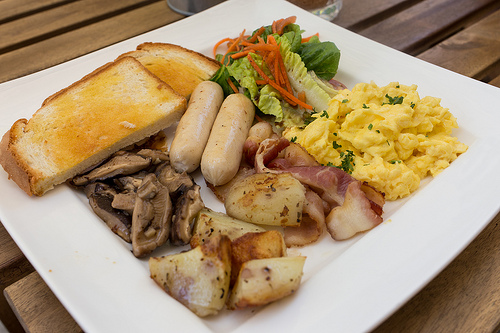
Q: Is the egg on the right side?
A: Yes, the egg is on the right of the image.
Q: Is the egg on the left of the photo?
A: No, the egg is on the right of the image.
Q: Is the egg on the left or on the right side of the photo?
A: The egg is on the right of the image.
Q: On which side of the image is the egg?
A: The egg is on the right of the image.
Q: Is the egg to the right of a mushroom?
A: Yes, the egg is to the right of a mushroom.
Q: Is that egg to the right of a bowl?
A: No, the egg is to the right of a mushroom.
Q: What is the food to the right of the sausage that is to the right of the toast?
A: The food is an egg.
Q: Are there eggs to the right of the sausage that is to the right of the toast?
A: Yes, there is an egg to the right of the sausage.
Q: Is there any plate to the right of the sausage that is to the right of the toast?
A: No, there is an egg to the right of the sausage.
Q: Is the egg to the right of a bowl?
A: No, the egg is to the right of the sausage.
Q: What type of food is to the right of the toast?
A: The food is an egg.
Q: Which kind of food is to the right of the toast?
A: The food is an egg.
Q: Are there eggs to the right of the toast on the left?
A: Yes, there is an egg to the right of the toast.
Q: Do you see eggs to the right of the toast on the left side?
A: Yes, there is an egg to the right of the toast.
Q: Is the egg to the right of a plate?
A: No, the egg is to the right of a toast.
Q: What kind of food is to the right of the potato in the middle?
A: The food is an egg.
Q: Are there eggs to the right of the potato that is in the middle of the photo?
A: Yes, there is an egg to the right of the potato.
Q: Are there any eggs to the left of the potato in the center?
A: No, the egg is to the right of the potato.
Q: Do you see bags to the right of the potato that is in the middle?
A: No, there is an egg to the right of the potato.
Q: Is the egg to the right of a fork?
A: No, the egg is to the right of the potato.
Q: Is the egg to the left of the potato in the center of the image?
A: No, the egg is to the right of the potato.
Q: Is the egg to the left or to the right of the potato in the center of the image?
A: The egg is to the right of the potato.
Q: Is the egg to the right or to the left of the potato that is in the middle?
A: The egg is to the right of the potato.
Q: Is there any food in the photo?
A: Yes, there is food.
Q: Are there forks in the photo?
A: No, there are no forks.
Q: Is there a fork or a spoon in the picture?
A: No, there are no forks or spoons.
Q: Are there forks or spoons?
A: No, there are no forks or spoons.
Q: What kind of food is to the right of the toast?
A: The food is a sausage.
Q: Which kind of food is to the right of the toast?
A: The food is a sausage.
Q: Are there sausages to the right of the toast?
A: Yes, there is a sausage to the right of the toast.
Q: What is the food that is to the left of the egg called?
A: The food is a sausage.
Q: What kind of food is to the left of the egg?
A: The food is a sausage.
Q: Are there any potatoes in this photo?
A: Yes, there is a potato.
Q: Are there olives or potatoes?
A: Yes, there is a potato.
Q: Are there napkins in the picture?
A: No, there are no napkins.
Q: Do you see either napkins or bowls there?
A: No, there are no napkins or bowls.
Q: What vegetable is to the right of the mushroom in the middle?
A: The vegetable is a potato.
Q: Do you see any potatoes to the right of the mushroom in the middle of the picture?
A: Yes, there is a potato to the right of the mushroom.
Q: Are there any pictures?
A: No, there are no pictures.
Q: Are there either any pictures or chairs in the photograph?
A: No, there are no pictures or chairs.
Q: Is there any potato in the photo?
A: Yes, there is a potato.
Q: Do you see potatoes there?
A: Yes, there is a potato.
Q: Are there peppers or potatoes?
A: Yes, there is a potato.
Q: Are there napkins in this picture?
A: No, there are no napkins.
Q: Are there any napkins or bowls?
A: No, there are no napkins or bowls.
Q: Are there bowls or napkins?
A: No, there are no napkins or bowls.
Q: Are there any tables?
A: Yes, there is a table.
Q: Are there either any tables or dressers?
A: Yes, there is a table.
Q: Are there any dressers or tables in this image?
A: Yes, there is a table.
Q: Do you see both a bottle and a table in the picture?
A: No, there is a table but no bottles.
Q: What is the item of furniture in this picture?
A: The piece of furniture is a table.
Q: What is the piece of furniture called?
A: The piece of furniture is a table.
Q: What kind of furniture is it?
A: The piece of furniture is a table.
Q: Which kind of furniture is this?
A: This is a table.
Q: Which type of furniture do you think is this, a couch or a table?
A: This is a table.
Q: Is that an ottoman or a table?
A: That is a table.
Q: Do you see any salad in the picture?
A: Yes, there is salad.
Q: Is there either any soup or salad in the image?
A: Yes, there is salad.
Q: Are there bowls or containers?
A: No, there are no containers or bowls.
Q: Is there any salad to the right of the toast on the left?
A: Yes, there is salad to the right of the toast.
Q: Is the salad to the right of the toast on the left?
A: Yes, the salad is to the right of the toast.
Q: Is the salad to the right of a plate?
A: No, the salad is to the right of the toast.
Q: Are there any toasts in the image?
A: Yes, there is a toast.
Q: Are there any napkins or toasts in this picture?
A: Yes, there is a toast.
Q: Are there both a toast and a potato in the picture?
A: Yes, there are both a toast and a potato.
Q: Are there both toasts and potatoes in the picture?
A: Yes, there are both a toast and a potato.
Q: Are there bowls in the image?
A: No, there are no bowls.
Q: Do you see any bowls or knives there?
A: No, there are no bowls or knives.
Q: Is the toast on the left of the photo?
A: Yes, the toast is on the left of the image.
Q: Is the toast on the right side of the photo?
A: No, the toast is on the left of the image.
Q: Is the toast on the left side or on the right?
A: The toast is on the left of the image.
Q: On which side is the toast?
A: The toast is on the left of the image.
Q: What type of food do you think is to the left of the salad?
A: The food is a toast.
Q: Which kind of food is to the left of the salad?
A: The food is a toast.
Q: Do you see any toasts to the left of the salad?
A: Yes, there is a toast to the left of the salad.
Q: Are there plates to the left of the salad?
A: No, there is a toast to the left of the salad.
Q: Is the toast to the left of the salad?
A: Yes, the toast is to the left of the salad.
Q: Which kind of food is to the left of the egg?
A: The food is a toast.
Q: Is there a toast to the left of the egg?
A: Yes, there is a toast to the left of the egg.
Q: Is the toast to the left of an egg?
A: Yes, the toast is to the left of an egg.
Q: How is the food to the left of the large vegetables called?
A: The food is a toast.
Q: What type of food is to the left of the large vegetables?
A: The food is a toast.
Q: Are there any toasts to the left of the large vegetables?
A: Yes, there is a toast to the left of the vegetables.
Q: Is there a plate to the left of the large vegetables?
A: No, there is a toast to the left of the veggies.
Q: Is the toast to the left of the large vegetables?
A: Yes, the toast is to the left of the veggies.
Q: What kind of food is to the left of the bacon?
A: The food is a toast.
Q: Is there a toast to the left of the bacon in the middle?
A: Yes, there is a toast to the left of the bacon.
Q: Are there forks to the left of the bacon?
A: No, there is a toast to the left of the bacon.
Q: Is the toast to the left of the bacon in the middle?
A: Yes, the toast is to the left of the bacon.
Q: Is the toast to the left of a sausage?
A: Yes, the toast is to the left of a sausage.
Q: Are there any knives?
A: No, there are no knives.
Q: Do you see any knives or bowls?
A: No, there are no knives or bowls.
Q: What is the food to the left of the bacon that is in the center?
A: The food is a mushroom.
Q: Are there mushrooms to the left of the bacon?
A: Yes, there is a mushroom to the left of the bacon.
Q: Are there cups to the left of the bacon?
A: No, there is a mushroom to the left of the bacon.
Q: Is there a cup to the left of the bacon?
A: No, there is a mushroom to the left of the bacon.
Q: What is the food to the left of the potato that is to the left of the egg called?
A: The food is a mushroom.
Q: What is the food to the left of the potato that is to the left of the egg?
A: The food is a mushroom.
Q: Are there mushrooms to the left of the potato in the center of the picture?
A: Yes, there is a mushroom to the left of the potato.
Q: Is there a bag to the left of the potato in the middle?
A: No, there is a mushroom to the left of the potato.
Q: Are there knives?
A: No, there are no knives.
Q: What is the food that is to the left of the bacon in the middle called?
A: The food is a mushroom.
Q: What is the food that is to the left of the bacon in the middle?
A: The food is a mushroom.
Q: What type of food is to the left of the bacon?
A: The food is a mushroom.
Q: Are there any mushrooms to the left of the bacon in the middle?
A: Yes, there is a mushroom to the left of the bacon.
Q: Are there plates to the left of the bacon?
A: No, there is a mushroom to the left of the bacon.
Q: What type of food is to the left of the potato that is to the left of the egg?
A: The food is a mushroom.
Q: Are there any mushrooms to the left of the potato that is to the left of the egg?
A: Yes, there is a mushroom to the left of the potato.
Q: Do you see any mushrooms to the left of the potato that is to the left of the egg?
A: Yes, there is a mushroom to the left of the potato.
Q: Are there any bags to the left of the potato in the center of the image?
A: No, there is a mushroom to the left of the potato.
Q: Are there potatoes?
A: Yes, there is a potato.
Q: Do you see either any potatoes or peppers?
A: Yes, there is a potato.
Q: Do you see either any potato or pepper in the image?
A: Yes, there is a potato.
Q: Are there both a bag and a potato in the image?
A: No, there is a potato but no bags.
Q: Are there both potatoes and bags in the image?
A: No, there is a potato but no bags.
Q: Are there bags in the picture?
A: No, there are no bags.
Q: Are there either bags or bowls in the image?
A: No, there are no bags or bowls.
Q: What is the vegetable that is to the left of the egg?
A: The vegetable is a potato.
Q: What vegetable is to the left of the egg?
A: The vegetable is a potato.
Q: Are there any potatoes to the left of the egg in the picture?
A: Yes, there is a potato to the left of the egg.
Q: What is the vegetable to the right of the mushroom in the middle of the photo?
A: The vegetable is a potato.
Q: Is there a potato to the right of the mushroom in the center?
A: Yes, there is a potato to the right of the mushroom.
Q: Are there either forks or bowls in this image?
A: No, there are no forks or bowls.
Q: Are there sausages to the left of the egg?
A: Yes, there is a sausage to the left of the egg.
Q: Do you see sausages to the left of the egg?
A: Yes, there is a sausage to the left of the egg.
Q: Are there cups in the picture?
A: No, there are no cups.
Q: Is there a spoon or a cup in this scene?
A: No, there are no cups or spoons.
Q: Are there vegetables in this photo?
A: Yes, there are vegetables.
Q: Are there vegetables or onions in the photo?
A: Yes, there are vegetables.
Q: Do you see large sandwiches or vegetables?
A: Yes, there are large vegetables.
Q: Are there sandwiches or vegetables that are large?
A: Yes, the vegetables are large.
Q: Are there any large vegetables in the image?
A: Yes, there are large vegetables.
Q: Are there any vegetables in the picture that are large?
A: Yes, there are vegetables that are large.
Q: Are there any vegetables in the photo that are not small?
A: Yes, there are large vegetables.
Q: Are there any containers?
A: No, there are no containers.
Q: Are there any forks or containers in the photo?
A: No, there are no containers or forks.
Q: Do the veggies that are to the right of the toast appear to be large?
A: Yes, the veggies are large.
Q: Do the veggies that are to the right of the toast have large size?
A: Yes, the veggies are large.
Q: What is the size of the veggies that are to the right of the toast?
A: The veggies are large.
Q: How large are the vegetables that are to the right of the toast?
A: The vegetables are large.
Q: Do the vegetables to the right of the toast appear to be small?
A: No, the veggies are large.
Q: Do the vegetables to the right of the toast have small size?
A: No, the veggies are large.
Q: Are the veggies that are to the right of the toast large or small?
A: The vegetables are large.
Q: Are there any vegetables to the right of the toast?
A: Yes, there are vegetables to the right of the toast.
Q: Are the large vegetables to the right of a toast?
A: Yes, the veggies are to the right of a toast.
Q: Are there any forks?
A: No, there are no forks.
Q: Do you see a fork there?
A: No, there are no forks.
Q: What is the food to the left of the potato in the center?
A: The food is a mushroom.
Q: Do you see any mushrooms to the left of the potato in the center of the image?
A: Yes, there is a mushroom to the left of the potato.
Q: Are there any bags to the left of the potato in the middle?
A: No, there is a mushroom to the left of the potato.